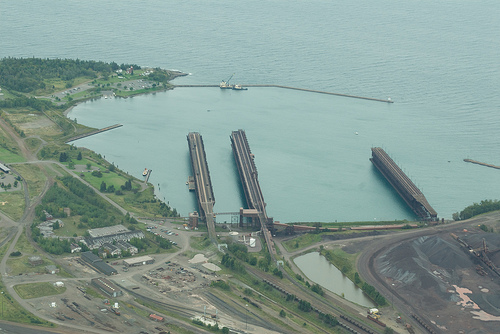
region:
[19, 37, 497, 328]
Picture taken from in the air.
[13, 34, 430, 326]
Picture taken during the day.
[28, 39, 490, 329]
Picture taken outdoors.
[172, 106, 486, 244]
Three jetties on the water.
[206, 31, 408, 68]
The waters are calm.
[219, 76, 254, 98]
A boat is parked.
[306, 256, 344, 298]
A small pool of water on the land.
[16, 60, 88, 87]
Trees against the back of the land.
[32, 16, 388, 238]
The day is hazy.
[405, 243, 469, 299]
Vacant empty land.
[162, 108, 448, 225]
numerous runways reach into water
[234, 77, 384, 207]
water is light blue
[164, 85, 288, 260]
runways are dark grey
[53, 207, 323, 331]
roads running around water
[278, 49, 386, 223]
water around runways is calm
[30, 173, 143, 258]
grove of trees near water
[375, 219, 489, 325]
dark grey quarry near water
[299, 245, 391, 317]
small lake near shore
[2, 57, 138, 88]
large forest at water's edge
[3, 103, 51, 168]
brown bare land by shore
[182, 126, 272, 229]
Couple of piers side by side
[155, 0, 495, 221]
Clear blue water with little activity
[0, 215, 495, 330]
Maze of roadways near the waterfront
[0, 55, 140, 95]
Green bushes by the waterfront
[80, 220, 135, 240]
Long, wide roofed building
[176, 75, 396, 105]
Long, thin barrier in the water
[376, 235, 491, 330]
Large, open tarmaced ground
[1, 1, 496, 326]
Small harbor with three piers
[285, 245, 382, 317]
Small pond near the shoreline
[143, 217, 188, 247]
Cars in an open parking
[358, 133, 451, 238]
This is a docking station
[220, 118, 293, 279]
This is a docking station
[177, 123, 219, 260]
This is a docking station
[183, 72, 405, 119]
This is a docking station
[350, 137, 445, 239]
This is a sheep docking station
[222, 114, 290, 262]
This is a sheep docking station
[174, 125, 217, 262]
This is a sheep docking station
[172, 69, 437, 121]
This is a sheep docking station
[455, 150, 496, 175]
This is a sheep docking station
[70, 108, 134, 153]
This is a sheep docking station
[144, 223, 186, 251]
the cars are parked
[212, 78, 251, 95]
the crane is white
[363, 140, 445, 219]
the dock is in the water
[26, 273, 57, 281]
the street is gray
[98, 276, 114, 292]
the roof is black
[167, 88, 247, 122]
the water is still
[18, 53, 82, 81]
the trees are healthy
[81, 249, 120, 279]
the building is black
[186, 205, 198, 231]
the tower is tall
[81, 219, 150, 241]
the building is big